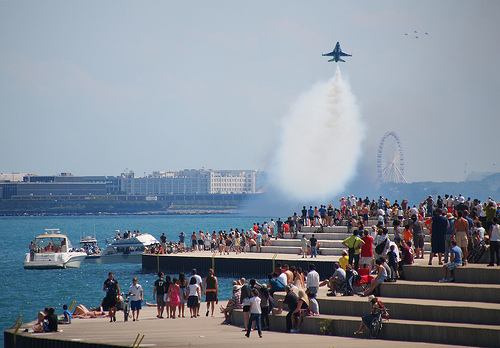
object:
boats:
[23, 226, 86, 270]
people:
[308, 233, 318, 258]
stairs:
[245, 244, 389, 254]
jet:
[320, 41, 354, 64]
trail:
[268, 64, 366, 203]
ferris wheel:
[377, 129, 407, 182]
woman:
[71, 305, 113, 318]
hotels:
[119, 167, 244, 199]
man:
[128, 277, 144, 321]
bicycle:
[121, 290, 129, 319]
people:
[30, 306, 59, 335]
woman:
[352, 293, 386, 335]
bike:
[367, 305, 386, 339]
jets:
[417, 35, 424, 39]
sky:
[0, 0, 500, 184]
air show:
[321, 42, 352, 63]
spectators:
[339, 229, 363, 271]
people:
[276, 286, 301, 336]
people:
[428, 209, 452, 264]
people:
[356, 260, 389, 298]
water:
[0, 215, 295, 347]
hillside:
[0, 197, 170, 212]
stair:
[229, 302, 499, 348]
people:
[203, 268, 219, 318]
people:
[102, 271, 123, 323]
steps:
[272, 292, 498, 324]